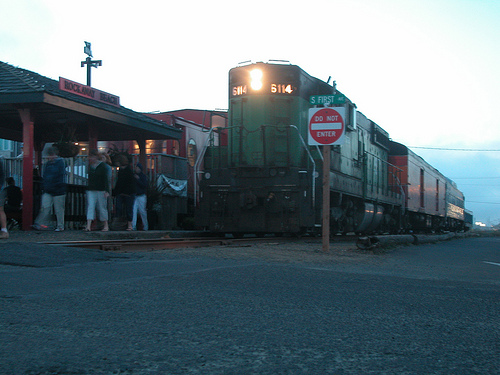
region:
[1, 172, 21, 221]
a person in the station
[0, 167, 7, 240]
a person in the station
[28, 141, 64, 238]
a person in the station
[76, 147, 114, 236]
a person in the station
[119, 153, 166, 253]
a person in the station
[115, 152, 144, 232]
a person in the station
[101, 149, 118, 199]
a person in the station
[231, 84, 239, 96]
a number on a train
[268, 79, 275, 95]
a number on a train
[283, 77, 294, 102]
a number on a train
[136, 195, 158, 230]
the leg of a person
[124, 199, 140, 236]
the leg of a person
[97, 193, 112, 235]
the leg of a person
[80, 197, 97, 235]
the leg of a person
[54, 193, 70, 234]
the leg of a person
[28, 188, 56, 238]
the leg of a person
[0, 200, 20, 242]
the leg of a person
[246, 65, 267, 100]
a light on a train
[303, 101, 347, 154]
a warning sign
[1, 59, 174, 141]
the roof of a some house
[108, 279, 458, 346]
road that the train station is on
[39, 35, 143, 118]
wind vale on top of train station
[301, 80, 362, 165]
street sign next to train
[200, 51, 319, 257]
first car on the train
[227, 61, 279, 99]
bright light on the front of train car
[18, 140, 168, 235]
people waiting to get on train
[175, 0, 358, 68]
top of first train car and cloudy day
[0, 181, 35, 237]
person sitting waiting to board train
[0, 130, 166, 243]
people tired of waiting to board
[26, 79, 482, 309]
a train station museum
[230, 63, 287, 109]
train lights are on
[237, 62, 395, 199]
the train car is green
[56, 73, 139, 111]
the sign is Rockaway Beach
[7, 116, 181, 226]
people at the train station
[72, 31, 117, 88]
crossroad street sign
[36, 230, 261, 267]
the train tracks are red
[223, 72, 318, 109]
train car is 6114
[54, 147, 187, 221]
fence at the train station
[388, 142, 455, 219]
the train car is red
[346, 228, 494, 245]
logs along the train tracks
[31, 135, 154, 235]
These people are blurry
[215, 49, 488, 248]
A train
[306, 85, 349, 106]
A sign for S First St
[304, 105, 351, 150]
A "Do Not Enter" sign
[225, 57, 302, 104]
The train has the number 6114 on it twice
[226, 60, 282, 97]
The train's light is on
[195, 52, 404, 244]
The first car in the train is green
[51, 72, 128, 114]
A sign for Rockaway Beach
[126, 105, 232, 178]
This building is red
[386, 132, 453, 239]
The second car on the train is red